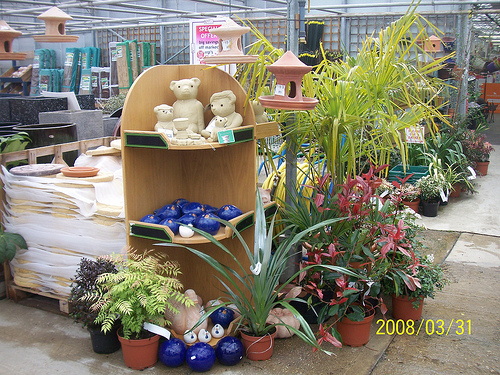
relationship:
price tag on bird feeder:
[272, 83, 285, 96] [257, 47, 317, 110]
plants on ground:
[260, 198, 429, 346] [0, 229, 498, 373]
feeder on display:
[30, 28, 107, 107] [46, 2, 104, 41]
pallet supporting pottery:
[12, 276, 76, 314] [19, 253, 79, 303]